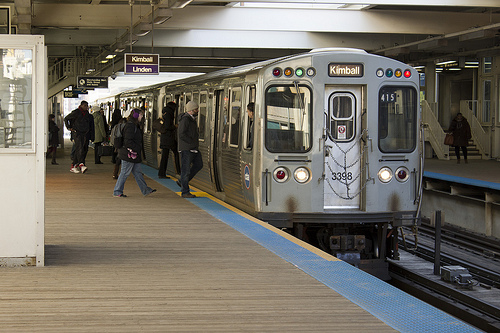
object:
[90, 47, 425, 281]
train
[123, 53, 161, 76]
sign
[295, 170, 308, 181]
light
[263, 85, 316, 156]
windshield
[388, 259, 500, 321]
rail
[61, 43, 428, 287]
transit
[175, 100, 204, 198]
passenger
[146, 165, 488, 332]
edge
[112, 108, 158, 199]
people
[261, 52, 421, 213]
front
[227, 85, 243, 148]
window